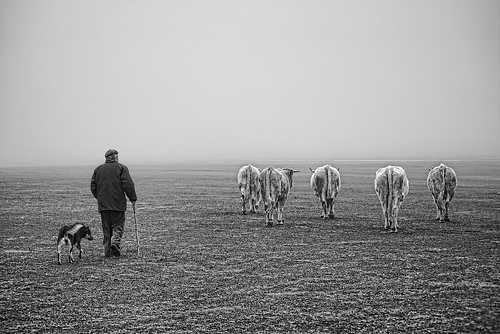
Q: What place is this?
A: It is a field.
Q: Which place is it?
A: It is a field.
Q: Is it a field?
A: Yes, it is a field.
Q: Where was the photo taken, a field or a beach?
A: It was taken at a field.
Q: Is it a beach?
A: No, it is a field.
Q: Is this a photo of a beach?
A: No, the picture is showing a field.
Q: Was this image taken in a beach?
A: No, the picture was taken in a field.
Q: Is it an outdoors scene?
A: Yes, it is outdoors.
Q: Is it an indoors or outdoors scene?
A: It is outdoors.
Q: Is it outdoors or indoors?
A: It is outdoors.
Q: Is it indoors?
A: No, it is outdoors.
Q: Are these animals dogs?
A: No, there are both dogs and cows.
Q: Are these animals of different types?
A: Yes, they are dogs and cows.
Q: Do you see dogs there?
A: Yes, there is a dog.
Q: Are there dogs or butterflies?
A: Yes, there is a dog.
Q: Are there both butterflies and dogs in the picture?
A: No, there is a dog but no butterflies.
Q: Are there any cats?
A: No, there are no cats.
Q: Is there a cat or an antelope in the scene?
A: No, there are no cats or antelopes.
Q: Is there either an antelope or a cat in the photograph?
A: No, there are no cats or antelopes.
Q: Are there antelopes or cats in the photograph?
A: No, there are no cats or antelopes.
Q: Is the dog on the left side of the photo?
A: Yes, the dog is on the left of the image.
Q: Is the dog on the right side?
A: No, the dog is on the left of the image.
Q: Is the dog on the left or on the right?
A: The dog is on the left of the image.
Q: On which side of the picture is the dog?
A: The dog is on the left of the image.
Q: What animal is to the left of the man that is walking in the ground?
A: The animal is a dog.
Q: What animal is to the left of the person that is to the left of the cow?
A: The animal is a dog.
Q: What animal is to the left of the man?
A: The animal is a dog.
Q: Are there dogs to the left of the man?
A: Yes, there is a dog to the left of the man.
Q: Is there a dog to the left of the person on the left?
A: Yes, there is a dog to the left of the man.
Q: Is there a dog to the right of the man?
A: No, the dog is to the left of the man.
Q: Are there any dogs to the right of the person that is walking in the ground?
A: No, the dog is to the left of the man.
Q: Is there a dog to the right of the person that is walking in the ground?
A: No, the dog is to the left of the man.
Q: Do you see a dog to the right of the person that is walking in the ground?
A: No, the dog is to the left of the man.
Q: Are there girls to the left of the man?
A: No, there is a dog to the left of the man.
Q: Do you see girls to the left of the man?
A: No, there is a dog to the left of the man.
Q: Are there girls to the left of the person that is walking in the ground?
A: No, there is a dog to the left of the man.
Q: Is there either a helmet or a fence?
A: No, there are no fences or helmets.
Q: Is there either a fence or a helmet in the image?
A: No, there are no fences or helmets.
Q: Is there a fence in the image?
A: No, there are no fences.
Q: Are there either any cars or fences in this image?
A: No, there are no fences or cars.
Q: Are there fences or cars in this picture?
A: No, there are no fences or cars.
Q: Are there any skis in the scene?
A: No, there are no skis.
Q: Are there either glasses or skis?
A: No, there are no skis or glasses.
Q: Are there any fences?
A: No, there are no fences.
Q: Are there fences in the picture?
A: No, there are no fences.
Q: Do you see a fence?
A: No, there are no fences.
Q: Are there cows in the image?
A: Yes, there is a cow.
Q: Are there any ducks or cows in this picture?
A: Yes, there is a cow.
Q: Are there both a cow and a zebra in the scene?
A: No, there is a cow but no zebras.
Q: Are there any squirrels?
A: No, there are no squirrels.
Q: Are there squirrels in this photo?
A: No, there are no squirrels.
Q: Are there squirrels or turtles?
A: No, there are no squirrels or turtles.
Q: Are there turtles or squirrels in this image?
A: No, there are no squirrels or turtles.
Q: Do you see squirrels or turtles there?
A: No, there are no squirrels or turtles.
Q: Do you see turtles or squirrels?
A: No, there are no squirrels or turtles.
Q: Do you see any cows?
A: Yes, there is a cow.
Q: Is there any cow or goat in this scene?
A: Yes, there is a cow.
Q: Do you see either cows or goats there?
A: Yes, there is a cow.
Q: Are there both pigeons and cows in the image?
A: No, there is a cow but no pigeons.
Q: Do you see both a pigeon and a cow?
A: No, there is a cow but no pigeons.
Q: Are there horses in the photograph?
A: No, there are no horses.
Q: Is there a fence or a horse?
A: No, there are no horses or fences.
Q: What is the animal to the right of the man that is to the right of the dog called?
A: The animal is a cow.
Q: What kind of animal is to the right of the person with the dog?
A: The animal is a cow.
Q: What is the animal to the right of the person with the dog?
A: The animal is a cow.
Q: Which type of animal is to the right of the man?
A: The animal is a cow.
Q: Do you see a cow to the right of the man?
A: Yes, there is a cow to the right of the man.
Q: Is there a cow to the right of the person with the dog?
A: Yes, there is a cow to the right of the man.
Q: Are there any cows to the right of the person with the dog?
A: Yes, there is a cow to the right of the man.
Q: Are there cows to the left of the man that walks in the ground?
A: No, the cow is to the right of the man.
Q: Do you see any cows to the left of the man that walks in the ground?
A: No, the cow is to the right of the man.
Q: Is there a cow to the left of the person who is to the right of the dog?
A: No, the cow is to the right of the man.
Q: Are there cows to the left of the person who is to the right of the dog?
A: No, the cow is to the right of the man.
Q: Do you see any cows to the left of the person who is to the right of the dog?
A: No, the cow is to the right of the man.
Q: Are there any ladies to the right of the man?
A: No, there is a cow to the right of the man.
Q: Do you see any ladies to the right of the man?
A: No, there is a cow to the right of the man.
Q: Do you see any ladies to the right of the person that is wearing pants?
A: No, there is a cow to the right of the man.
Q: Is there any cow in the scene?
A: Yes, there is a cow.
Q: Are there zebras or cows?
A: Yes, there is a cow.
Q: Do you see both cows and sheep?
A: No, there is a cow but no sheep.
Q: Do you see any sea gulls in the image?
A: No, there are no sea gulls.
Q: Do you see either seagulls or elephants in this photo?
A: No, there are no seagulls or elephants.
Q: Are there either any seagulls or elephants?
A: No, there are no seagulls or elephants.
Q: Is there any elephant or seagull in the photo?
A: No, there are no seagulls or elephants.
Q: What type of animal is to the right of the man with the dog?
A: The animal is a cow.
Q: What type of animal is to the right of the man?
A: The animal is a cow.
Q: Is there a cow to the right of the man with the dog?
A: Yes, there is a cow to the right of the man.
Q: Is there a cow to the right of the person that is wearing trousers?
A: Yes, there is a cow to the right of the man.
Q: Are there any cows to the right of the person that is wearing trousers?
A: Yes, there is a cow to the right of the man.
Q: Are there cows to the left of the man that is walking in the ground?
A: No, the cow is to the right of the man.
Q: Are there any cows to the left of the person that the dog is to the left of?
A: No, the cow is to the right of the man.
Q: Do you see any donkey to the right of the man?
A: No, there is a cow to the right of the man.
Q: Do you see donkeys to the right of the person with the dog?
A: No, there is a cow to the right of the man.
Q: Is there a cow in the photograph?
A: Yes, there is a cow.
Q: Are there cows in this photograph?
A: Yes, there is a cow.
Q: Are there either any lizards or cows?
A: Yes, there is a cow.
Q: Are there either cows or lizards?
A: Yes, there is a cow.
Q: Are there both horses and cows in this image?
A: No, there is a cow but no horses.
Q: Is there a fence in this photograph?
A: No, there are no fences.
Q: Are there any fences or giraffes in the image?
A: No, there are no fences or giraffes.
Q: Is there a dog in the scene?
A: Yes, there is a dog.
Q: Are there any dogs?
A: Yes, there is a dog.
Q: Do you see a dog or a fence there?
A: Yes, there is a dog.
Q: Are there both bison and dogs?
A: No, there is a dog but no bison.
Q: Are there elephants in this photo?
A: No, there are no elephants.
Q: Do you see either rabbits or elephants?
A: No, there are no elephants or rabbits.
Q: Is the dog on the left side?
A: Yes, the dog is on the left of the image.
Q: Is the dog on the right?
A: No, the dog is on the left of the image.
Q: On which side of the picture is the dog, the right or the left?
A: The dog is on the left of the image.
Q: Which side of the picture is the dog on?
A: The dog is on the left of the image.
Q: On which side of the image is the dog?
A: The dog is on the left of the image.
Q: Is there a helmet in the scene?
A: No, there are no helmets.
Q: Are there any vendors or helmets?
A: No, there are no helmets or vendors.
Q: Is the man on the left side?
A: Yes, the man is on the left of the image.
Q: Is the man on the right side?
A: No, the man is on the left of the image.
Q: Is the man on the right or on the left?
A: The man is on the left of the image.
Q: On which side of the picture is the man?
A: The man is on the left of the image.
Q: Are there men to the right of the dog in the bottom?
A: Yes, there is a man to the right of the dog.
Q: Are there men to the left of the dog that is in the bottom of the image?
A: No, the man is to the right of the dog.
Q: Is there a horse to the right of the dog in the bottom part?
A: No, there is a man to the right of the dog.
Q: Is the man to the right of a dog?
A: Yes, the man is to the right of a dog.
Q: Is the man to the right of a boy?
A: No, the man is to the right of a dog.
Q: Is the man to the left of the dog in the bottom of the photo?
A: No, the man is to the right of the dog.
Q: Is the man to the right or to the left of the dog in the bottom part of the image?
A: The man is to the right of the dog.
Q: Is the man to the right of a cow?
A: No, the man is to the left of a cow.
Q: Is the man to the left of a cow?
A: Yes, the man is to the left of a cow.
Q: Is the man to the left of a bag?
A: No, the man is to the left of a cow.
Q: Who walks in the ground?
A: The man walks in the ground.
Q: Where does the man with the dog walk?
A: The man walks in the ground.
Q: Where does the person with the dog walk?
A: The man walks in the ground.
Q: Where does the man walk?
A: The man walks in the ground.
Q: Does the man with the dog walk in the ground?
A: Yes, the man walks in the ground.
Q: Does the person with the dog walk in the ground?
A: Yes, the man walks in the ground.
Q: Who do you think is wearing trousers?
A: The man is wearing trousers.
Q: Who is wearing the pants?
A: The man is wearing trousers.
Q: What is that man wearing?
A: The man is wearing trousers.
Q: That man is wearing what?
A: The man is wearing trousers.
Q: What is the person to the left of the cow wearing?
A: The man is wearing trousers.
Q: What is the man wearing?
A: The man is wearing trousers.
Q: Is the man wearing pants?
A: Yes, the man is wearing pants.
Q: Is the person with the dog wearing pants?
A: Yes, the man is wearing pants.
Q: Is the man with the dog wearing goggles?
A: No, the man is wearing pants.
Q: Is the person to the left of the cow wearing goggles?
A: No, the man is wearing pants.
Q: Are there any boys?
A: No, there are no boys.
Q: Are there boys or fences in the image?
A: No, there are no boys or fences.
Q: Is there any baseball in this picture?
A: No, there are no baseballs.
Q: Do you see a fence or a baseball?
A: No, there are no baseballs or fences.